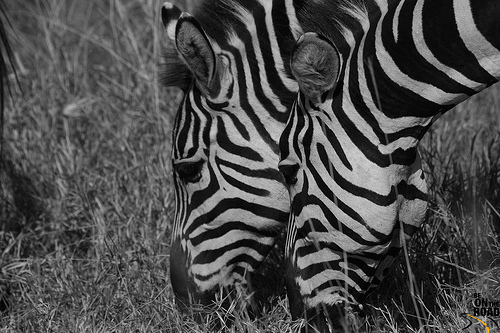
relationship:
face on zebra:
[145, 65, 299, 298] [171, 15, 459, 303]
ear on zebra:
[288, 28, 342, 101] [128, 6, 442, 298]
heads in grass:
[148, 20, 438, 314] [5, 183, 484, 313]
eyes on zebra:
[176, 149, 216, 188] [128, 6, 442, 298]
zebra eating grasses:
[270, 0, 499, 330] [199, 243, 462, 331]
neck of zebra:
[239, 13, 469, 157] [159, 8, 439, 318]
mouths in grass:
[168, 234, 374, 328] [17, 160, 158, 309]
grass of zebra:
[17, 160, 158, 309] [159, 8, 439, 318]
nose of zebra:
[163, 254, 383, 331] [159, 8, 439, 318]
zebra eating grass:
[149, 9, 475, 329] [1, 1, 484, 330]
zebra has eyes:
[134, 5, 367, 324] [175, 148, 216, 193]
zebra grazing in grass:
[134, 0, 333, 330] [1, 1, 484, 330]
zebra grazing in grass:
[270, 0, 499, 330] [1, 1, 484, 330]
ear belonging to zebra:
[159, 0, 185, 43] [134, 0, 333, 330]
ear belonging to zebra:
[286, 29, 345, 99] [270, 0, 499, 330]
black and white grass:
[43, 214, 108, 281] [72, 312, 121, 333]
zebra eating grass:
[134, 0, 333, 330] [21, 8, 447, 323]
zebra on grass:
[270, 0, 499, 330] [41, 31, 376, 299]